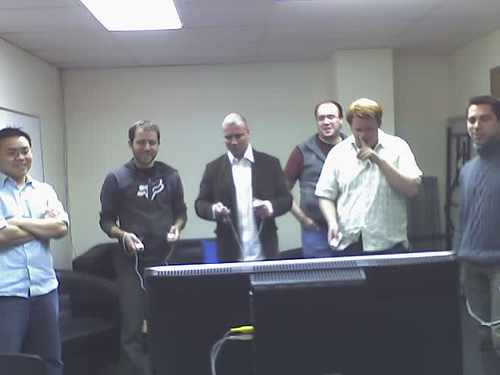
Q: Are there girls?
A: No, there are no girls.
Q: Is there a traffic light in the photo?
A: No, there are no traffic lights.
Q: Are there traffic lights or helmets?
A: No, there are no traffic lights or helmets.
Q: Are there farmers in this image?
A: No, there are no farmers.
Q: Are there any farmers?
A: No, there are no farmers.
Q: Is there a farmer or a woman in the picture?
A: No, there are no farmers or women.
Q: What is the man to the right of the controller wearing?
A: The man is wearing a shirt.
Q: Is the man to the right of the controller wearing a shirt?
A: Yes, the man is wearing a shirt.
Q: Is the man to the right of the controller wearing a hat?
A: No, the man is wearing a shirt.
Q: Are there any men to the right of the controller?
A: Yes, there is a man to the right of the controller.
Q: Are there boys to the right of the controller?
A: No, there is a man to the right of the controller.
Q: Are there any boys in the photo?
A: No, there are no boys.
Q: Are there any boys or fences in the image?
A: No, there are no boys or fences.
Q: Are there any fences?
A: No, there are no fences.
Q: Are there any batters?
A: No, there are no batters.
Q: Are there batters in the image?
A: No, there are no batters.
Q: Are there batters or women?
A: No, there are no batters or women.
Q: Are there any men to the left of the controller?
A: Yes, there is a man to the left of the controller.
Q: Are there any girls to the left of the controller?
A: No, there is a man to the left of the controller.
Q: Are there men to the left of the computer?
A: Yes, there is a man to the left of the computer.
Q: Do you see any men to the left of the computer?
A: Yes, there is a man to the left of the computer.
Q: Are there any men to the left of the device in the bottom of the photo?
A: Yes, there is a man to the left of the computer.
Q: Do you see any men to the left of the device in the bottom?
A: Yes, there is a man to the left of the computer.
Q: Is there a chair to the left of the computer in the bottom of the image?
A: No, there is a man to the left of the computer.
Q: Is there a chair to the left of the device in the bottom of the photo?
A: No, there is a man to the left of the computer.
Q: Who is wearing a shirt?
A: The man is wearing a shirt.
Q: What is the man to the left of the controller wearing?
A: The man is wearing a shirt.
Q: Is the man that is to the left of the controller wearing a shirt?
A: Yes, the man is wearing a shirt.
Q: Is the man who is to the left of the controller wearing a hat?
A: No, the man is wearing a shirt.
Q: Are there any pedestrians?
A: No, there are no pedestrians.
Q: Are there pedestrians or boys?
A: No, there are no pedestrians or boys.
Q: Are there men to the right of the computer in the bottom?
A: Yes, there is a man to the right of the computer.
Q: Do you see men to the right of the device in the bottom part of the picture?
A: Yes, there is a man to the right of the computer.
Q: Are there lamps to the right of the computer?
A: No, there is a man to the right of the computer.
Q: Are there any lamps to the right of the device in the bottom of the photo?
A: No, there is a man to the right of the computer.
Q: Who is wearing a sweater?
A: The man is wearing a sweater.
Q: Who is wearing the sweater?
A: The man is wearing a sweater.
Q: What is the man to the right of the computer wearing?
A: The man is wearing a sweater.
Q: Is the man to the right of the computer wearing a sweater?
A: Yes, the man is wearing a sweater.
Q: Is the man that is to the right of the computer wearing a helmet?
A: No, the man is wearing a sweater.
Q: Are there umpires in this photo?
A: No, there are no umpires.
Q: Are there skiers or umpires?
A: No, there are no umpires or skiers.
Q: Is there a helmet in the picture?
A: No, there are no helmets.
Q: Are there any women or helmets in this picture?
A: No, there are no helmets or women.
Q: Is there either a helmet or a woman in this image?
A: No, there are no helmets or women.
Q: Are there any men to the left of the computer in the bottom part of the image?
A: Yes, there is a man to the left of the computer.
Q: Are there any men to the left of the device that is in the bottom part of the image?
A: Yes, there is a man to the left of the computer.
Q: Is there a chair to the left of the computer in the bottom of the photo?
A: No, there is a man to the left of the computer.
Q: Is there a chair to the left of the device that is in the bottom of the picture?
A: No, there is a man to the left of the computer.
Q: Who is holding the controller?
A: The man is holding the controller.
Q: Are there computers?
A: Yes, there is a computer.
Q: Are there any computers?
A: Yes, there is a computer.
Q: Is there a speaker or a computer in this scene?
A: Yes, there is a computer.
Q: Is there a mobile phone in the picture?
A: No, there are no cell phones.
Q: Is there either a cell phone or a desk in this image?
A: No, there are no cell phones or desks.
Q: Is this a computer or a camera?
A: This is a computer.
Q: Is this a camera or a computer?
A: This is a computer.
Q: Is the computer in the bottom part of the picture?
A: Yes, the computer is in the bottom of the image.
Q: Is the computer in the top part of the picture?
A: No, the computer is in the bottom of the image.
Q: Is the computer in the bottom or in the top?
A: The computer is in the bottom of the image.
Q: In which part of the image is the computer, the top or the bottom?
A: The computer is in the bottom of the image.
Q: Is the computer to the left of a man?
A: No, the computer is to the right of a man.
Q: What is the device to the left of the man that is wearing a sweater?
A: The device is a computer.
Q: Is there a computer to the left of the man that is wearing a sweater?
A: Yes, there is a computer to the left of the man.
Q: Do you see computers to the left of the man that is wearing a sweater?
A: Yes, there is a computer to the left of the man.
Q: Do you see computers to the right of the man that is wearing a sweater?
A: No, the computer is to the left of the man.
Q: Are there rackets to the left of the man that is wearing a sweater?
A: No, there is a computer to the left of the man.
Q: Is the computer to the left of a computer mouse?
A: No, the computer is to the left of a man.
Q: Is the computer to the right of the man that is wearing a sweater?
A: No, the computer is to the left of the man.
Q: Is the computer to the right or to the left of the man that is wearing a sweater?
A: The computer is to the left of the man.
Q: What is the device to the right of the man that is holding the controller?
A: The device is a computer.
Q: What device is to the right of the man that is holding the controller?
A: The device is a computer.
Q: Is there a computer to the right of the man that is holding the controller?
A: Yes, there is a computer to the right of the man.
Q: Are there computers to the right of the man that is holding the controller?
A: Yes, there is a computer to the right of the man.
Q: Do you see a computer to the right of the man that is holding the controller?
A: Yes, there is a computer to the right of the man.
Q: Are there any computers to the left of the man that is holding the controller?
A: No, the computer is to the right of the man.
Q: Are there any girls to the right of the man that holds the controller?
A: No, there is a computer to the right of the man.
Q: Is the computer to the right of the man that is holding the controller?
A: Yes, the computer is to the right of the man.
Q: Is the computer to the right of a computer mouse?
A: No, the computer is to the right of the man.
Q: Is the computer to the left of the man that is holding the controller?
A: No, the computer is to the right of the man.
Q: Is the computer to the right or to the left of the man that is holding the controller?
A: The computer is to the right of the man.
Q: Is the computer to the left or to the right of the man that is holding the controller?
A: The computer is to the right of the man.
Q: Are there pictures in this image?
A: No, there are no pictures.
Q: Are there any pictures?
A: No, there are no pictures.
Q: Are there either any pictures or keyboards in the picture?
A: No, there are no pictures or keyboards.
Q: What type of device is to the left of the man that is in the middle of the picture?
A: The device is a controller.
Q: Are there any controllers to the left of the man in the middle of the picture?
A: Yes, there is a controller to the left of the man.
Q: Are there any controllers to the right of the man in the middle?
A: No, the controller is to the left of the man.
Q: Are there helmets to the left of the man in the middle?
A: No, there is a controller to the left of the man.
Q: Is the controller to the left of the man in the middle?
A: Yes, the controller is to the left of the man.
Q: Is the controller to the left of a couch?
A: No, the controller is to the left of the man.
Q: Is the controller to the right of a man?
A: No, the controller is to the left of a man.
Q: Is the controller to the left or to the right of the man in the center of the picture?
A: The controller is to the left of the man.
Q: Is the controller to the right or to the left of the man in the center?
A: The controller is to the left of the man.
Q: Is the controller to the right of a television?
A: No, the controller is to the right of a man.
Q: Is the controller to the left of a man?
A: No, the controller is to the right of a man.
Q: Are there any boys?
A: No, there are no boys.